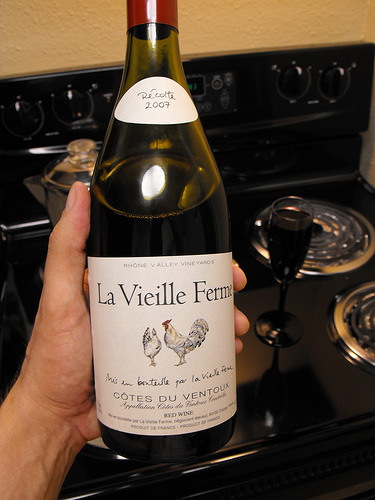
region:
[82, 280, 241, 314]
writing on the bottle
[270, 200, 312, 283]
a glass of wine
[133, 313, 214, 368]
rosters on the wrapper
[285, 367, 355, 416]
the stove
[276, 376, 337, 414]
the stove is black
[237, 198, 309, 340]
a glass of wine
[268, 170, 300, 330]
a full glass of wine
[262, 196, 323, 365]
a full wine glass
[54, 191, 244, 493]
hand holding a bottle of wine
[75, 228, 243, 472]
a bottle iwth label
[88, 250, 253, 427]
a bottle of wine with label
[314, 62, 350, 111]
a knob on stove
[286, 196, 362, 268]
a burner on stove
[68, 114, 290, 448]
a bottle of wine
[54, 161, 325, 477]
a hand holding a bottle of wine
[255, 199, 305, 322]
a wine glass on stove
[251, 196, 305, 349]
a stove with wine glass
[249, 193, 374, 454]
a black kitchen stove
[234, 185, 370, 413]
a stove that is balck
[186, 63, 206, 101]
a clock on the stove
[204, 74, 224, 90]
a button on a stove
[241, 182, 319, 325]
a glass of full wine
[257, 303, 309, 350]
base of drinking glass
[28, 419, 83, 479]
veins in man's hand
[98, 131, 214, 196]
gold color on wine bottle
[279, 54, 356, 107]
black knobs on stove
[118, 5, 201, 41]
red top on wine bottle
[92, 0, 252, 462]
hand holding bottle of wine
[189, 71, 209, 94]
green words on stove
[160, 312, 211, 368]
white rooster on wine label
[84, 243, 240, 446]
white label on wine bottle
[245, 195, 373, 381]
black stove burners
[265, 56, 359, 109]
black knobs on top of black stove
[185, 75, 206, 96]
digital window on top of black stove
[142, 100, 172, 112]
year handwritten on label on wine bottle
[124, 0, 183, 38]
red top on wine bottle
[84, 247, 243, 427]
white label on red wine bottele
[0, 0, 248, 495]
white hand holding red bottle of wine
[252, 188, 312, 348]
wine glass on counter with wine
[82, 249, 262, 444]
wine is French and red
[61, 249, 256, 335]
words on the bottle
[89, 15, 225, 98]
top part of bottle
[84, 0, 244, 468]
bottle of wine in person's hand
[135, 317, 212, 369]
rooster and hen on wine label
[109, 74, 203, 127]
wine label depicting a year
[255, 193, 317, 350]
glass full of wine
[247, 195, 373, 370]
two electric burners on stovetop range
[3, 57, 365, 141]
whole bunch of knobs on stovetop range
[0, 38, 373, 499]
black stovetop range for cooking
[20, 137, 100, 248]
percolator on stovetop range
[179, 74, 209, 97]
digital clock on stovetop range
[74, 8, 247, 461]
a bottle of wine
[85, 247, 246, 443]
label on the bottle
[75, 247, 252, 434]
the label is white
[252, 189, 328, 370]
a glass of wine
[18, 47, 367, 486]
a shiny black stove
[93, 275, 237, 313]
black writing on label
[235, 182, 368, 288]
burner on the stove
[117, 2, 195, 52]
red trim on bottle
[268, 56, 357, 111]
a pair of knobs